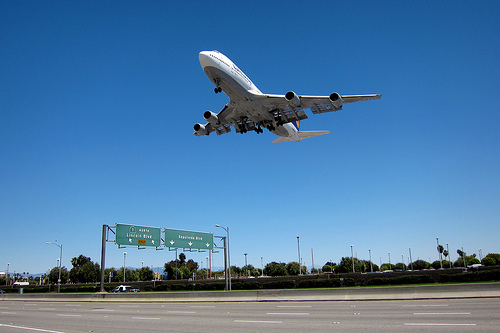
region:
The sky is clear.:
[17, 27, 162, 185]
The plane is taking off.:
[170, 27, 352, 157]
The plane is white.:
[160, 34, 328, 144]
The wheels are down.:
[203, 69, 282, 154]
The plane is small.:
[154, 8, 395, 205]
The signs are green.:
[88, 200, 236, 254]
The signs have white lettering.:
[86, 214, 251, 272]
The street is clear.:
[12, 235, 347, 327]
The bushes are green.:
[261, 248, 423, 284]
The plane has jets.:
[183, 31, 366, 175]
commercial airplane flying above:
[161, 47, 351, 182]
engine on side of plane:
[323, 92, 353, 110]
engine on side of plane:
[277, 88, 300, 108]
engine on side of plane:
[203, 112, 215, 125]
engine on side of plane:
[188, 122, 208, 142]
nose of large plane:
[188, 41, 227, 83]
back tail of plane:
[271, 125, 328, 153]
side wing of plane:
[291, 85, 379, 113]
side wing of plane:
[182, 105, 239, 140]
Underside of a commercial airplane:
[175, 40, 385, 156]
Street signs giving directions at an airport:
[90, 215, 235, 300]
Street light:
[40, 230, 70, 290]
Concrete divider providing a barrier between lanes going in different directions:
[2, 276, 372, 306]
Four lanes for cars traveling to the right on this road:
[6, 290, 433, 330]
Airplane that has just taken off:
[168, 36, 394, 148]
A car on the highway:
[98, 278, 148, 299]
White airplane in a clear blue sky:
[18, 11, 470, 198]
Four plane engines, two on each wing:
[189, 88, 387, 140]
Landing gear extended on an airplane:
[210, 81, 292, 139]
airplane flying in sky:
[190, 47, 381, 149]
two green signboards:
[112, 224, 222, 249]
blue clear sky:
[0, 1, 498, 268]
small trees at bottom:
[27, 254, 498, 286]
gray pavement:
[0, 287, 499, 331]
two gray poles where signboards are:
[92, 225, 233, 285]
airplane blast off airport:
[192, 41, 379, 161]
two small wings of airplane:
[189, 85, 381, 132]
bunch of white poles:
[4, 239, 489, 279]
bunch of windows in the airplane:
[232, 61, 256, 86]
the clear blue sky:
[12, 22, 171, 177]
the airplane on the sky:
[190, 43, 386, 149]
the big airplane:
[190, 43, 385, 144]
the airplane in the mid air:
[188, 43, 394, 153]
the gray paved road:
[24, 298, 141, 330]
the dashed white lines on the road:
[53, 310, 173, 328]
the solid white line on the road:
[1, 315, 69, 331]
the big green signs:
[95, 213, 228, 252]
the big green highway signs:
[110, 212, 215, 254]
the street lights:
[30, 222, 413, 292]